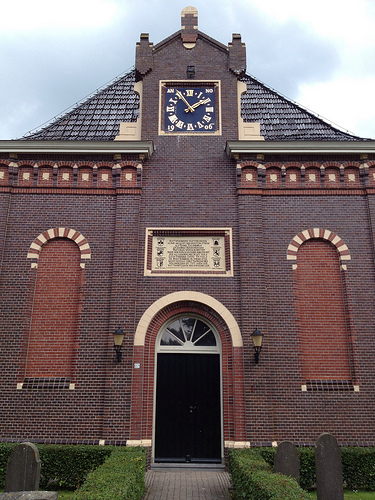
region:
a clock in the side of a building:
[155, 78, 223, 137]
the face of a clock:
[166, 89, 214, 130]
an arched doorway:
[133, 290, 253, 472]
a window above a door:
[157, 313, 221, 351]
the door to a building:
[152, 351, 227, 467]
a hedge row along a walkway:
[224, 445, 293, 499]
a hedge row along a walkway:
[78, 442, 152, 498]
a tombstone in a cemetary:
[3, 441, 48, 489]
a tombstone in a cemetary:
[310, 429, 347, 498]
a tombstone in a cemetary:
[267, 440, 305, 484]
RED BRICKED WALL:
[310, 247, 333, 376]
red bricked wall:
[46, 264, 66, 362]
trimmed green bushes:
[98, 454, 134, 499]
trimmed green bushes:
[235, 455, 280, 498]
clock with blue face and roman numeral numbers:
[158, 78, 226, 133]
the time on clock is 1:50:
[166, 82, 219, 132]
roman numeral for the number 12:
[185, 86, 197, 100]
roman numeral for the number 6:
[186, 122, 194, 132]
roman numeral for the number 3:
[203, 105, 216, 114]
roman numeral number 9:
[162, 106, 179, 116]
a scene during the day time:
[0, 0, 373, 495]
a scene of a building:
[2, 3, 373, 498]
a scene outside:
[0, 3, 368, 496]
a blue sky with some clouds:
[2, 6, 368, 135]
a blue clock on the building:
[149, 70, 227, 142]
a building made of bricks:
[12, 38, 374, 449]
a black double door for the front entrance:
[146, 305, 232, 481]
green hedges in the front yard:
[73, 438, 280, 494]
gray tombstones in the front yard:
[2, 423, 366, 492]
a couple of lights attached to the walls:
[99, 318, 289, 367]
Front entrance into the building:
[127, 285, 248, 469]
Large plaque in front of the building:
[143, 225, 235, 279]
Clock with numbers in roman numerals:
[156, 76, 223, 138]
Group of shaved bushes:
[3, 440, 373, 498]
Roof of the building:
[6, 8, 370, 140]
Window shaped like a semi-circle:
[153, 312, 225, 353]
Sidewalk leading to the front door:
[145, 461, 230, 498]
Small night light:
[110, 327, 127, 362]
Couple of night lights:
[111, 325, 265, 366]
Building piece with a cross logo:
[177, 6, 199, 49]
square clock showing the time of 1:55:
[159, 79, 222, 135]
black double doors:
[156, 352, 220, 462]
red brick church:
[0, 6, 374, 442]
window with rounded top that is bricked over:
[17, 225, 90, 391]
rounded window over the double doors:
[152, 312, 222, 465]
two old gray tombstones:
[269, 433, 342, 498]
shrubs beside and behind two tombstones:
[226, 431, 373, 497]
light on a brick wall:
[112, 323, 126, 359]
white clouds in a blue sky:
[4, 0, 374, 142]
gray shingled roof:
[13, 66, 369, 139]